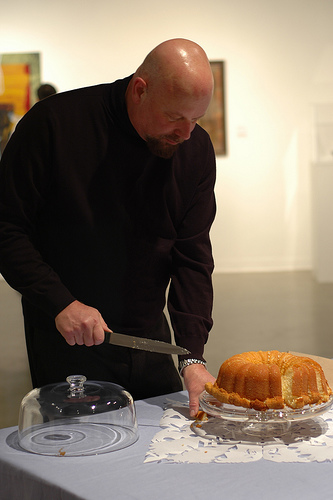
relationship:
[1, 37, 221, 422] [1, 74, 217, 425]
man wears clothes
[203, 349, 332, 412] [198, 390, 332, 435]
cake on cake stand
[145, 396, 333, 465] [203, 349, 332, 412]
doily under cake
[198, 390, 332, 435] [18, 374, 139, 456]
cake stand has cover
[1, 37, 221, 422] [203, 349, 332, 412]
man cuts cake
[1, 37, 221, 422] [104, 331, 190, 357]
man holding knife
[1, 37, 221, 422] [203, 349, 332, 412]
man cutting cake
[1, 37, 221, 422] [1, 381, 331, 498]
man standing at table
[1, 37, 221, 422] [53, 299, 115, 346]
man has hand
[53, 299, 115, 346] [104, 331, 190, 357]
hand holds knife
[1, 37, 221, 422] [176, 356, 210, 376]
man has wrist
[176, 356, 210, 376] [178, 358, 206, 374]
wrist has watch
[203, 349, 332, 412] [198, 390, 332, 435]
cake on top of cake stand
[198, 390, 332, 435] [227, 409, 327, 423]
cake stand has edge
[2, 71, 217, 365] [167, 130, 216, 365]
shirt has sleeve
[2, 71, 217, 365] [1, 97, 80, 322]
shirt has sleeve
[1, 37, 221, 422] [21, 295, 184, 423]
man wears pants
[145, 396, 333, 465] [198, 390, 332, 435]
doily underneath cake stand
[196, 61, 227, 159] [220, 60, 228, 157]
picture has edge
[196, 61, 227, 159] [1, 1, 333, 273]
picture hanging on wall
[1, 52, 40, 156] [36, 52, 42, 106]
picture has edge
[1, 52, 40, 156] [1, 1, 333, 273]
picture hanging on wall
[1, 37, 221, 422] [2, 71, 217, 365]
man wearing shirt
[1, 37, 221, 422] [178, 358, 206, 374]
man wearing watch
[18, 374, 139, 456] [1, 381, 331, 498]
cover on top of table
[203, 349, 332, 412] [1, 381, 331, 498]
cake on table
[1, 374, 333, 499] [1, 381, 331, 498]
table cloth on table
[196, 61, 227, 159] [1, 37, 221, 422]
picture behind man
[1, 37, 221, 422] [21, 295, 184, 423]
man wearing pants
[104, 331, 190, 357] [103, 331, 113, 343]
knife has handle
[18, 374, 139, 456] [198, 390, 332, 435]
cover belongs to cake stand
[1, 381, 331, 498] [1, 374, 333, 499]
table has table cloth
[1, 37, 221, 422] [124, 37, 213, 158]
man has head